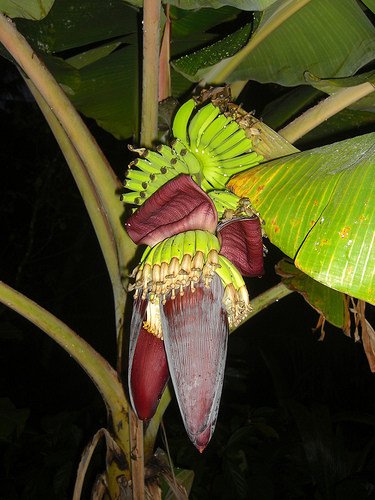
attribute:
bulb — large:
[161, 272, 229, 452]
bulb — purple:
[155, 281, 227, 457]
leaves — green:
[1, 0, 374, 319]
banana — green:
[169, 91, 190, 142]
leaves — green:
[58, 417, 195, 498]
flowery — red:
[155, 273, 234, 461]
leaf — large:
[229, 129, 373, 338]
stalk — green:
[124, 405, 148, 495]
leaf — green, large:
[170, 2, 374, 89]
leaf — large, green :
[219, 127, 373, 304]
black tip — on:
[170, 139, 176, 145]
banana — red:
[91, 92, 323, 303]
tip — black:
[174, 146, 193, 158]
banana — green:
[224, 156, 258, 165]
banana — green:
[173, 90, 197, 145]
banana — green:
[189, 103, 213, 150]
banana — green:
[217, 125, 244, 156]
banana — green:
[183, 147, 199, 172]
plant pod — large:
[162, 363, 261, 477]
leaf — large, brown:
[20, 309, 120, 389]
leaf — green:
[218, 126, 371, 285]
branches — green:
[2, 21, 176, 308]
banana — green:
[154, 137, 175, 162]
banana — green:
[136, 146, 170, 170]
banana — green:
[127, 157, 158, 174]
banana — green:
[117, 167, 153, 183]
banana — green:
[116, 175, 148, 192]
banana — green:
[118, 190, 140, 203]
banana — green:
[208, 187, 239, 220]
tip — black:
[114, 191, 126, 203]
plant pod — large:
[118, 169, 219, 247]